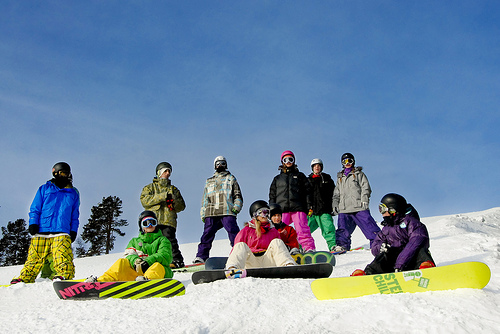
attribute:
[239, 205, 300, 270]
girl — sitting in snow, blonde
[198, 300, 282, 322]
snow — white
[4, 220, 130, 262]
trees — evergreen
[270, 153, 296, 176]
helmet — pink, black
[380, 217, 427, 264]
jacket — purple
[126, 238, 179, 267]
jacket — green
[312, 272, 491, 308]
snowboard — yellow, green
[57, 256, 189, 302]
snowboard — yellow black, pink, black yellow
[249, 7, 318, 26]
sky — clear, blue, distant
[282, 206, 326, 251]
pants — pink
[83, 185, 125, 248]
tree — green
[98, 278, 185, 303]
stripes — yellow, black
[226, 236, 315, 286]
snow pants — white